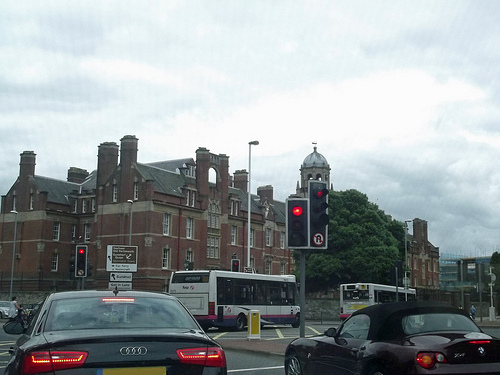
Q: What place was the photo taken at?
A: It was taken at the street.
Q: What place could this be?
A: It is a street.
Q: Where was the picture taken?
A: It was taken at the street.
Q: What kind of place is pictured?
A: It is a street.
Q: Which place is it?
A: It is a street.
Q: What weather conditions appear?
A: It is cloudy.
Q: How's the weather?
A: It is cloudy.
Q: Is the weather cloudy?
A: Yes, it is cloudy.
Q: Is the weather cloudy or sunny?
A: It is cloudy.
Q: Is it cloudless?
A: No, it is cloudy.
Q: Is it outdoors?
A: Yes, it is outdoors.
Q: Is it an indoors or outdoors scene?
A: It is outdoors.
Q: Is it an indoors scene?
A: No, it is outdoors.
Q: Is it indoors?
A: No, it is outdoors.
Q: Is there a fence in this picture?
A: No, there are no fences.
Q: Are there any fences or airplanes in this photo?
A: No, there are no fences or airplanes.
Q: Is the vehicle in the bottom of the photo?
A: Yes, the vehicle is in the bottom of the image.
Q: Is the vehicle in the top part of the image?
A: No, the vehicle is in the bottom of the image.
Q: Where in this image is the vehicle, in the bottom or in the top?
A: The vehicle is in the bottom of the image.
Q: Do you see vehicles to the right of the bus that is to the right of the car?
A: Yes, there is a vehicle to the right of the bus.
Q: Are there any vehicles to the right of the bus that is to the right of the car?
A: Yes, there is a vehicle to the right of the bus.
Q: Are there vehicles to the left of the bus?
A: No, the vehicle is to the right of the bus.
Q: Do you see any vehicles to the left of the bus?
A: No, the vehicle is to the right of the bus.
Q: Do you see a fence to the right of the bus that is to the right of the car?
A: No, there is a vehicle to the right of the bus.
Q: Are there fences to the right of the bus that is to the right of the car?
A: No, there is a vehicle to the right of the bus.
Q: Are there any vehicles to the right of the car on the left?
A: Yes, there is a vehicle to the right of the car.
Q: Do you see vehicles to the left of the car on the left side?
A: No, the vehicle is to the right of the car.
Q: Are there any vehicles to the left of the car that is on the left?
A: No, the vehicle is to the right of the car.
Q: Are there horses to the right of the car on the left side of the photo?
A: No, there is a vehicle to the right of the car.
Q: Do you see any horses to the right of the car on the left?
A: No, there is a vehicle to the right of the car.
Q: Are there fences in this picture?
A: No, there are no fences.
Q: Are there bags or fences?
A: No, there are no fences or bags.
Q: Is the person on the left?
A: Yes, the person is on the left of the image.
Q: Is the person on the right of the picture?
A: No, the person is on the left of the image.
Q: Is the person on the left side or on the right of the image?
A: The person is on the left of the image.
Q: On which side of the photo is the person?
A: The person is on the left of the image.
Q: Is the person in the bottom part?
A: Yes, the person is in the bottom of the image.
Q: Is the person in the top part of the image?
A: No, the person is in the bottom of the image.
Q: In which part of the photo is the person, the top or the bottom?
A: The person is in the bottom of the image.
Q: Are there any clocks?
A: No, there are no clocks.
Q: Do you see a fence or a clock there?
A: No, there are no clocks or fences.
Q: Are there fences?
A: No, there are no fences.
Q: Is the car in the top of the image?
A: No, the car is in the bottom of the image.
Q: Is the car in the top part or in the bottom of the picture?
A: The car is in the bottom of the image.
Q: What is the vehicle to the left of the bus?
A: The vehicle is a car.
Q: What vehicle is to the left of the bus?
A: The vehicle is a car.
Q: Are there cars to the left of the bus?
A: Yes, there is a car to the left of the bus.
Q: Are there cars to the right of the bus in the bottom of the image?
A: No, the car is to the left of the bus.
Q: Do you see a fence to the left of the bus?
A: No, there is a car to the left of the bus.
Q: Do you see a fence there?
A: No, there are no fences.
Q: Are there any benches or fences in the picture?
A: No, there are no fences or benches.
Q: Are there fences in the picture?
A: No, there are no fences.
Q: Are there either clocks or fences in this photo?
A: No, there are no fences or clocks.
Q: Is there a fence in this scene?
A: No, there are no fences.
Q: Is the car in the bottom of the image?
A: Yes, the car is in the bottom of the image.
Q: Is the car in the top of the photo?
A: No, the car is in the bottom of the image.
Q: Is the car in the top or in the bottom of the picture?
A: The car is in the bottom of the image.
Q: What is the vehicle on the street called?
A: The vehicle is a car.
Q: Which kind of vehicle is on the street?
A: The vehicle is a car.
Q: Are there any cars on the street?
A: Yes, there is a car on the street.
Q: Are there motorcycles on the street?
A: No, there is a car on the street.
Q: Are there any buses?
A: Yes, there is a bus.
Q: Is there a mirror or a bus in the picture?
A: Yes, there is a bus.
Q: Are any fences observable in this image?
A: No, there are no fences.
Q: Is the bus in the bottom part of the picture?
A: Yes, the bus is in the bottom of the image.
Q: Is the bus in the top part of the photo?
A: No, the bus is in the bottom of the image.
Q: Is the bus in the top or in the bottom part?
A: The bus is in the bottom of the image.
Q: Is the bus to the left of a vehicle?
A: Yes, the bus is to the left of a vehicle.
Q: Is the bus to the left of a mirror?
A: No, the bus is to the left of a vehicle.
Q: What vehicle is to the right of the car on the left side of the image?
A: The vehicle is a bus.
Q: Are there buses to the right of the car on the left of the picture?
A: Yes, there is a bus to the right of the car.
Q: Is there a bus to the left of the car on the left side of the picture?
A: No, the bus is to the right of the car.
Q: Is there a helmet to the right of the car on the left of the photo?
A: No, there is a bus to the right of the car.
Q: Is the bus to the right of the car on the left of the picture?
A: Yes, the bus is to the right of the car.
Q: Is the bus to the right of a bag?
A: No, the bus is to the right of the car.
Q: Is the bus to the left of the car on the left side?
A: No, the bus is to the right of the car.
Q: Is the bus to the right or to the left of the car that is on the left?
A: The bus is to the right of the car.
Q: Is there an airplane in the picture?
A: No, there are no airplanes.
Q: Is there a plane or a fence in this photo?
A: No, there are no airplanes or fences.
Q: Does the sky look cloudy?
A: Yes, the sky is cloudy.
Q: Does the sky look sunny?
A: No, the sky is cloudy.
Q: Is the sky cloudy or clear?
A: The sky is cloudy.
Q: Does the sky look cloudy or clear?
A: The sky is cloudy.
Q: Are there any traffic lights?
A: Yes, there is a traffic light.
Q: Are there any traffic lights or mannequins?
A: Yes, there is a traffic light.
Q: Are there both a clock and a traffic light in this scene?
A: No, there is a traffic light but no clocks.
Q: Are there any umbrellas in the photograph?
A: No, there are no umbrellas.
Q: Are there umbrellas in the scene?
A: No, there are no umbrellas.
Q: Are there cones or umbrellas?
A: No, there are no umbrellas or cones.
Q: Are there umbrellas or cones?
A: No, there are no umbrellas or cones.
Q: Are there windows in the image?
A: Yes, there is a window.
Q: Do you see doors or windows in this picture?
A: Yes, there is a window.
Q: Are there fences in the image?
A: No, there are no fences.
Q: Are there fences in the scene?
A: No, there are no fences.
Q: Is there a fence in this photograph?
A: No, there are no fences.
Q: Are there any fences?
A: No, there are no fences.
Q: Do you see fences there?
A: No, there are no fences.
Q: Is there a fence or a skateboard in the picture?
A: No, there are no fences or skateboards.